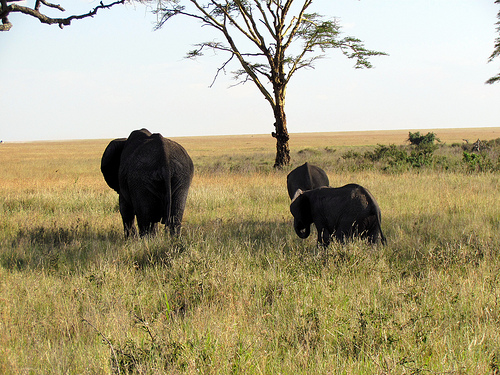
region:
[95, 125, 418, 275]
three elephants are seen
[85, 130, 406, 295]
elephants are grey in color.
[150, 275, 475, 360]
grass are green in color.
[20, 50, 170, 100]
sky is white in color.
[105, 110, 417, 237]
elephants are walking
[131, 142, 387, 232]
elephants are facing backwards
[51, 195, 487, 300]
shadow are in the grass.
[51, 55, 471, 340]
daytime picture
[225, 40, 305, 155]
woods are brown in color.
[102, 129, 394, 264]
elephants are walking in the grass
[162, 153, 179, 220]
tail of an elephant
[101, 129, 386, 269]
a herd of elephants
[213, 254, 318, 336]
tall brown and green grass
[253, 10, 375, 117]
a tree with green leaves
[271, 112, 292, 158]
trunk of a tree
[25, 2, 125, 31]
a tree branch without leaves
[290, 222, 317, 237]
the trunk of an elephant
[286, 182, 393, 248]
a elephant standing in the grass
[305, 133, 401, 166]
brown grass in the savanah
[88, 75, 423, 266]
elephants by standing by a tree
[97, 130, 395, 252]
Elephants standing in high grass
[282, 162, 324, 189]
Backside and tail of small elephant.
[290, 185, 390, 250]
Small elephant, facing left.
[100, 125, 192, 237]
Large, adult elephant, facing away from camera, towards tree.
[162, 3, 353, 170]
Spindly tree, showing minimal leaves.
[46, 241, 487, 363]
Tall, pale, dehydrated grass with darker patches, here and there.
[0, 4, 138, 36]
High, gnarled and weathered tree branch, showing no leaves.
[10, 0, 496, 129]
Seemingly endless, bleached blue sky.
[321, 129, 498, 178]
Patches of darker, green vegetation on slightly higher ground.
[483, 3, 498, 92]
Leafy twigs, cutting across sky.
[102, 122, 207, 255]
Large, adult elephant, facing away.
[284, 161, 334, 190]
Smaller elephant, facing away.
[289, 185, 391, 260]
Left profile of small elephant with trunk near mouth.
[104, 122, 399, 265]
Elephants standing in tall grass.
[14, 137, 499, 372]
Grass in shades of green, white and beige, mostly dehydrated looking.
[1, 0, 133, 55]
Gnarled tree branch.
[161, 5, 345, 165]
Spindly tree with few leaves.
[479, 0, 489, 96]
Leaves showing, from branch cropped from photo.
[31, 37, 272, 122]
Pale, blue sky with minimal clouding.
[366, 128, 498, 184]
Area of darker vegetation, right.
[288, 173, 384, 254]
Baby elephant walking in the wilderness.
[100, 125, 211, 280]
Adult elephant walking in the wilderness.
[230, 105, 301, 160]
Tree trunk in the wilderness.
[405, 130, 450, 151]
Bush in the wilderness.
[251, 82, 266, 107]
Tree branch in the wilderness.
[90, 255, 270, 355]
Dry grass in the wilderness.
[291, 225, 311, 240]
Baby elephants trunk in the wilderness.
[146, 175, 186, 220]
Adult elephants tail in the wilderness.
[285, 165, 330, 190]
Other baby elephant in the wilderness.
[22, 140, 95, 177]
Open plain in the wilderness.